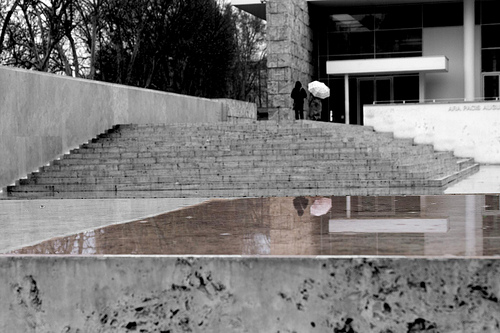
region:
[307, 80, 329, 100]
White umbrella in an open position.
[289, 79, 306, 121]
Person wearing all back.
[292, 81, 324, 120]
Two people near a building.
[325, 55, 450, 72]
Awning over building door.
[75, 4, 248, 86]
Tangle of trees.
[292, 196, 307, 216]
Reflection of person in all black.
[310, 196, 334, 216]
Reflection of umbrella in stone.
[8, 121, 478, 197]
Steps leading up to a building.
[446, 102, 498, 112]
The name of the building on wall.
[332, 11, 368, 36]
Lights on ceiling top.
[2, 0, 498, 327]
the photo is in black and white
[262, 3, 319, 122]
the column is rock textured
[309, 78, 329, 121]
the woman is holding an umbrella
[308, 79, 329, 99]
the umbrella is white in color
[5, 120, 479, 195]
the steps are two sided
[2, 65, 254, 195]
the wall runs across the steps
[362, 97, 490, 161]
the wall is light in color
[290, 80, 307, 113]
the man is wearing is wearing black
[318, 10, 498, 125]
the facade is made of glass windows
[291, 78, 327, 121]
two people are atop the steps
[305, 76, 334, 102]
a white umbrella over the person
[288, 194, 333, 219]
a reflection of the people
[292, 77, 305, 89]
the head of a woman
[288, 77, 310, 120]
a woman wearing black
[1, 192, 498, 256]
a large brown tile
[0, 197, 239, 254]
a large gray tile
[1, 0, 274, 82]
a gray sky behind the trees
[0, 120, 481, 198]
a set of stairs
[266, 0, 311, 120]
a stone wall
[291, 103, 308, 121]
the legs of a person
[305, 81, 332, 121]
A person carrying an umbrella.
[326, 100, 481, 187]
Stairs leading to a landing.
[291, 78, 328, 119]
Two people stand at the top of the stairs.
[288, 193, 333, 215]
A reflection of two people.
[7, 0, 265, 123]
A black and white picture of trees and a wall.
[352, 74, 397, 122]
An entrance to the building.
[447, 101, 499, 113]
Writing on the wall.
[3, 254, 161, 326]
Granite, marble or stone material.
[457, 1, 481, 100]
A single column.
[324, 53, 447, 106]
Over hang to the entrance.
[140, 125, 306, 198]
the steps are gray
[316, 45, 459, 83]
the structure is white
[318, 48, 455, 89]
the structure is rectangle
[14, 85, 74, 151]
the wall is gray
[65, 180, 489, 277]
the water is smooth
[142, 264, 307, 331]
the wall is rough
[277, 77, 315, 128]
the man is standing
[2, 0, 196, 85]
there are many trees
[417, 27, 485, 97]
the wall is white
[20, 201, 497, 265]
the pool is large